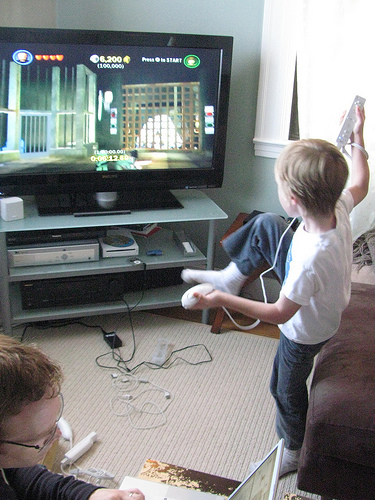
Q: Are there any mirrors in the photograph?
A: No, there are no mirrors.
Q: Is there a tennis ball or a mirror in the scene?
A: No, there are no mirrors or tennis balls.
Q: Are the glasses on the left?
A: Yes, the glasses are on the left of the image.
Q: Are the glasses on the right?
A: No, the glasses are on the left of the image.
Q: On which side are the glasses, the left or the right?
A: The glasses are on the left of the image.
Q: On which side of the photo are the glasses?
A: The glasses are on the left of the image.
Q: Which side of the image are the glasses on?
A: The glasses are on the left of the image.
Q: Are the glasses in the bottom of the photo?
A: Yes, the glasses are in the bottom of the image.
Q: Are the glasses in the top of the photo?
A: No, the glasses are in the bottom of the image.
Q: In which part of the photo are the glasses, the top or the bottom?
A: The glasses are in the bottom of the image.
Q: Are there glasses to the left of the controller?
A: Yes, there are glasses to the left of the controller.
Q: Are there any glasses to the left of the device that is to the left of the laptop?
A: Yes, there are glasses to the left of the controller.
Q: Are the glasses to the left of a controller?
A: Yes, the glasses are to the left of a controller.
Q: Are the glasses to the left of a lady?
A: No, the glasses are to the left of a controller.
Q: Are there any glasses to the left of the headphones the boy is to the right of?
A: Yes, there are glasses to the left of the headphones.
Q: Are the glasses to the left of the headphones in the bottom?
A: Yes, the glasses are to the left of the headphones.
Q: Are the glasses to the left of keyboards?
A: No, the glasses are to the left of the headphones.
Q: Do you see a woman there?
A: No, there are no women.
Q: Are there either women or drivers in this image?
A: No, there are no women or drivers.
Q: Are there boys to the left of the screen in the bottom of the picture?
A: Yes, there is a boy to the left of the screen.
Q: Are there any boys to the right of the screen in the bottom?
A: No, the boy is to the left of the screen.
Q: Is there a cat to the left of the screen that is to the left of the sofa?
A: No, there is a boy to the left of the screen.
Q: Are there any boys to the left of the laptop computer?
A: Yes, there is a boy to the left of the laptop computer.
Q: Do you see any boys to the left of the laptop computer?
A: Yes, there is a boy to the left of the laptop computer.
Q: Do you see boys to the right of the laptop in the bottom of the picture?
A: No, the boy is to the left of the laptop.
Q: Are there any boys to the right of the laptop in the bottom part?
A: No, the boy is to the left of the laptop.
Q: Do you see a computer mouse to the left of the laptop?
A: No, there is a boy to the left of the laptop.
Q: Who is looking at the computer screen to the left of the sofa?
A: The boy is looking at the screen.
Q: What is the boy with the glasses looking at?
A: The boy is looking at the screen.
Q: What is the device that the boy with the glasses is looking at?
A: The device is a screen.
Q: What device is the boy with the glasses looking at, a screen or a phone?
A: The boy is looking at a screen.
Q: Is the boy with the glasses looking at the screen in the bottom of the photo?
A: Yes, the boy is looking at the screen.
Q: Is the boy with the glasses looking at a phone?
A: No, the boy is looking at the screen.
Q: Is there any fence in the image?
A: No, there are no fences.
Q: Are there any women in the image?
A: No, there are no women.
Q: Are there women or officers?
A: No, there are no women or officers.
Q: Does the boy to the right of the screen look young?
A: Yes, the boy is young.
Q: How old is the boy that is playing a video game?
A: The boy is young.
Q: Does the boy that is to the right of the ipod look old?
A: No, the boy is young.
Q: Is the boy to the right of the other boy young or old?
A: The boy is young.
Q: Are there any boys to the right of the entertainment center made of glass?
A: Yes, there is a boy to the right of the entertainment center.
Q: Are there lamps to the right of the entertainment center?
A: No, there is a boy to the right of the entertainment center.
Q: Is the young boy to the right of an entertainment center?
A: Yes, the boy is to the right of an entertainment center.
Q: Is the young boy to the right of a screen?
A: Yes, the boy is to the right of a screen.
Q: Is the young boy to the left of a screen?
A: No, the boy is to the right of a screen.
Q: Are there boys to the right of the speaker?
A: Yes, there is a boy to the right of the speaker.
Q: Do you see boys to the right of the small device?
A: Yes, there is a boy to the right of the speaker.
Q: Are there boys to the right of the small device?
A: Yes, there is a boy to the right of the speaker.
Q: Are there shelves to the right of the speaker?
A: No, there is a boy to the right of the speaker.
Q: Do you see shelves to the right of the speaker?
A: No, there is a boy to the right of the speaker.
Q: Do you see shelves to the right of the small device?
A: No, there is a boy to the right of the speaker.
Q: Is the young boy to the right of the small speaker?
A: Yes, the boy is to the right of the speaker.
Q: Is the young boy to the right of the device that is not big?
A: Yes, the boy is to the right of the speaker.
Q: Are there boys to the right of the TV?
A: Yes, there is a boy to the right of the TV.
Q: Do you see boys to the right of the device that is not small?
A: Yes, there is a boy to the right of the TV.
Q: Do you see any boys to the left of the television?
A: No, the boy is to the right of the television.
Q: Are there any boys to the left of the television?
A: No, the boy is to the right of the television.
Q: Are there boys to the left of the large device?
A: No, the boy is to the right of the television.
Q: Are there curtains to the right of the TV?
A: No, there is a boy to the right of the TV.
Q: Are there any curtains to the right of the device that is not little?
A: No, there is a boy to the right of the TV.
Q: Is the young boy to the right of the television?
A: Yes, the boy is to the right of the television.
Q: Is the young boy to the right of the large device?
A: Yes, the boy is to the right of the television.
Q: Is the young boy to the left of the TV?
A: No, the boy is to the right of the TV.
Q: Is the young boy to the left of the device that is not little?
A: No, the boy is to the right of the TV.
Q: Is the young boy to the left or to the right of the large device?
A: The boy is to the right of the TV.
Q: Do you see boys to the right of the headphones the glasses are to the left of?
A: Yes, there is a boy to the right of the headphones.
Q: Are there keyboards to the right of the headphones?
A: No, there is a boy to the right of the headphones.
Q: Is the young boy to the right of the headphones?
A: Yes, the boy is to the right of the headphones.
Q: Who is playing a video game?
A: The boy is playing a video game.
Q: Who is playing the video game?
A: The boy is playing a video game.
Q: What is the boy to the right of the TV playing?
A: The boy is playing a video game.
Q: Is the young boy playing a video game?
A: Yes, the boy is playing a video game.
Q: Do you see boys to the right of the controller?
A: Yes, there is a boy to the right of the controller.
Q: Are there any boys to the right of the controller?
A: Yes, there is a boy to the right of the controller.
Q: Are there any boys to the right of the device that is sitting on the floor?
A: Yes, there is a boy to the right of the controller.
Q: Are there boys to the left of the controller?
A: No, the boy is to the right of the controller.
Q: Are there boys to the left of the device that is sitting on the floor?
A: No, the boy is to the right of the controller.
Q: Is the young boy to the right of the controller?
A: Yes, the boy is to the right of the controller.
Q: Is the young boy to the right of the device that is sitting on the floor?
A: Yes, the boy is to the right of the controller.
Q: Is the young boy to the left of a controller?
A: No, the boy is to the right of a controller.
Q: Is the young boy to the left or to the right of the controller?
A: The boy is to the right of the controller.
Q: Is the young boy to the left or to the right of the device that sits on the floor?
A: The boy is to the right of the controller.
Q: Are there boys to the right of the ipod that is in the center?
A: Yes, there is a boy to the right of the ipod.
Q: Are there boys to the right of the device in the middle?
A: Yes, there is a boy to the right of the ipod.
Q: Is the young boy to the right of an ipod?
A: Yes, the boy is to the right of an ipod.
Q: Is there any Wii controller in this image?
A: Yes, there is a Wii controller.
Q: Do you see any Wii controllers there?
A: Yes, there is a Wii controller.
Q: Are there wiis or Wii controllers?
A: Yes, there is a Wii controller.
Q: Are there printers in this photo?
A: No, there are no printers.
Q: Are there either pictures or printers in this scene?
A: No, there are no printers or pictures.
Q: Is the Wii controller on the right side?
A: Yes, the Wii controller is on the right of the image.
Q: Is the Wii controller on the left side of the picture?
A: No, the Wii controller is on the right of the image.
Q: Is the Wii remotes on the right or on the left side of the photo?
A: The Wii remotes is on the right of the image.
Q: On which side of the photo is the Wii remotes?
A: The Wii remotes is on the right of the image.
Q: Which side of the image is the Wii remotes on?
A: The Wii remotes is on the right of the image.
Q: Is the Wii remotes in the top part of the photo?
A: Yes, the Wii remotes is in the top of the image.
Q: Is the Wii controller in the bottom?
A: No, the Wii controller is in the top of the image.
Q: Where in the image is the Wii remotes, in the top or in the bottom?
A: The Wii remotes is in the top of the image.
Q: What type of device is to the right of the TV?
A: The device is a Wii controller.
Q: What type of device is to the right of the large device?
A: The device is a Wii controller.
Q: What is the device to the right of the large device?
A: The device is a Wii controller.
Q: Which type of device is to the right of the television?
A: The device is a Wii controller.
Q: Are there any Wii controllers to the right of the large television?
A: Yes, there is a Wii controller to the right of the TV.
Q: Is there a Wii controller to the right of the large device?
A: Yes, there is a Wii controller to the right of the TV.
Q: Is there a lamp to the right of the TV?
A: No, there is a Wii controller to the right of the TV.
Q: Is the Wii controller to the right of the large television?
A: Yes, the Wii controller is to the right of the TV.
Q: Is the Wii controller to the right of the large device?
A: Yes, the Wii controller is to the right of the TV.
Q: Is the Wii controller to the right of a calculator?
A: No, the Wii controller is to the right of the TV.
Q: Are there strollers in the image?
A: No, there are no strollers.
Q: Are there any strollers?
A: No, there are no strollers.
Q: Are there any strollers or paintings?
A: No, there are no strollers or paintings.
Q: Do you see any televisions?
A: Yes, there is a television.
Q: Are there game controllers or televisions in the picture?
A: Yes, there is a television.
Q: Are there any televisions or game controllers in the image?
A: Yes, there is a television.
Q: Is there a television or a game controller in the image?
A: Yes, there is a television.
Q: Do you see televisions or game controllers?
A: Yes, there is a television.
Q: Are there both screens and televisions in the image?
A: Yes, there are both a television and a screen.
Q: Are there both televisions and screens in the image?
A: Yes, there are both a television and a screen.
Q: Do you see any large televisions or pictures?
A: Yes, there is a large television.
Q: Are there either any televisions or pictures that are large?
A: Yes, the television is large.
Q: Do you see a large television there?
A: Yes, there is a large television.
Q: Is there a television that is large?
A: Yes, there is a television that is large.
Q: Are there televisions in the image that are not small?
A: Yes, there is a large television.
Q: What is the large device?
A: The device is a television.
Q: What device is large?
A: The device is a television.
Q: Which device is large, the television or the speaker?
A: The television is large.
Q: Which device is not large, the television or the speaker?
A: The speaker is not large.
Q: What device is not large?
A: The device is a speaker.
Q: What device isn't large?
A: The device is a speaker.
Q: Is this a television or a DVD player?
A: This is a television.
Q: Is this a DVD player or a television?
A: This is a television.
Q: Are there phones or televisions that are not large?
A: No, there is a television but it is large.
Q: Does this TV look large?
A: Yes, the TV is large.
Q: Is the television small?
A: No, the television is large.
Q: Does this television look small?
A: No, the television is large.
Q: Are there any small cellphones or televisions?
A: No, there is a television but it is large.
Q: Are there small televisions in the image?
A: No, there is a television but it is large.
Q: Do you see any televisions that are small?
A: No, there is a television but it is large.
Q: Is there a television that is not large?
A: No, there is a television but it is large.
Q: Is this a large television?
A: Yes, this is a large television.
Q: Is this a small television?
A: No, this is a large television.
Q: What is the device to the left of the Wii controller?
A: The device is a television.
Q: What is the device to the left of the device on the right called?
A: The device is a television.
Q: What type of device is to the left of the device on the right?
A: The device is a television.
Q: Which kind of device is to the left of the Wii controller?
A: The device is a television.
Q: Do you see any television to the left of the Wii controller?
A: Yes, there is a television to the left of the Wii controller.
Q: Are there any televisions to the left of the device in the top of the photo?
A: Yes, there is a television to the left of the Wii controller.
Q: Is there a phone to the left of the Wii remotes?
A: No, there is a television to the left of the Wii remotes.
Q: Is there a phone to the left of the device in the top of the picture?
A: No, there is a television to the left of the Wii remotes.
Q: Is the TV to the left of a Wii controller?
A: Yes, the TV is to the left of a Wii controller.